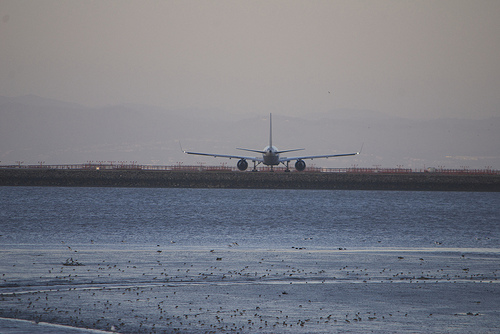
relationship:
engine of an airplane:
[294, 159, 306, 171] [183, 113, 358, 173]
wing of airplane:
[280, 153, 355, 162] [183, 113, 358, 173]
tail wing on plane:
[264, 105, 278, 154] [176, 107, 363, 175]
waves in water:
[1, 185, 499, 250] [0, 182, 497, 297]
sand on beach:
[216, 297, 393, 328] [7, 222, 482, 324]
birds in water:
[193, 261, 351, 330] [199, 193, 416, 253]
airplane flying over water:
[183, 113, 358, 173] [0, 185, 485, 331]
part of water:
[346, 223, 375, 253] [0, 185, 485, 331]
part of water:
[276, 234, 295, 264] [281, 211, 346, 250]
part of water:
[366, 220, 391, 268] [0, 185, 485, 331]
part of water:
[388, 210, 413, 239] [85, 218, 445, 312]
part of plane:
[280, 153, 294, 163] [183, 110, 360, 172]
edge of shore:
[2, 316, 108, 332] [34, 277, 494, 332]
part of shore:
[397, 194, 431, 234] [2, 163, 499, 192]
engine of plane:
[237, 157, 247, 171] [174, 113, 408, 193]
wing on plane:
[289, 147, 361, 169] [191, 115, 366, 177]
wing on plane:
[184, 147, 249, 171] [179, 106, 362, 191]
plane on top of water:
[178, 129, 358, 173] [7, 173, 483, 242]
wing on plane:
[280, 153, 355, 162] [178, 102, 365, 166]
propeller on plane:
[287, 150, 309, 173] [183, 127, 333, 179]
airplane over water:
[180, 113, 364, 172] [0, 188, 480, 257]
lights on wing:
[178, 142, 362, 162] [158, 131, 238, 176]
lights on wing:
[178, 142, 362, 162] [308, 139, 362, 176]